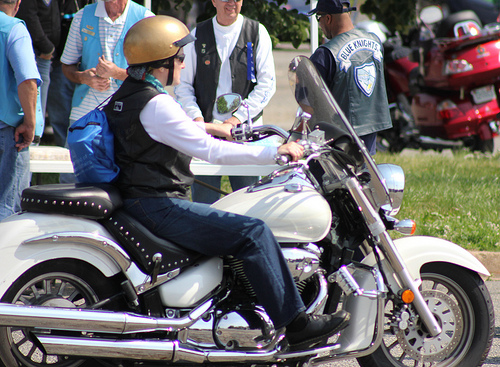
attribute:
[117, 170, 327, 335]
pants — long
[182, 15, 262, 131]
vest — dark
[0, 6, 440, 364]
people — gathered, together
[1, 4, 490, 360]
people — enjoying the day, out in sunshine, part of club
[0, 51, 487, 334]
motorcycle — white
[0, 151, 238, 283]
seat — black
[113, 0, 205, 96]
helmet — black, golden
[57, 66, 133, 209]
bag — blue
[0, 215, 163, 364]
wheel — black, back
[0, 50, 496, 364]
motorcycle — black, white, handle, big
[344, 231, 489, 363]
wheel — black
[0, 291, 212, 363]
pipe — exhaust, metal, gray, large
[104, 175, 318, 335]
jeans — blue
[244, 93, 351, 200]
bar — handle, chrome, metal, gray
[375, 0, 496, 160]
motorcycle — red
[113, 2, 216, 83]
helmet — brown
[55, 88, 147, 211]
backpack — blue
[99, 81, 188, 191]
vest — blue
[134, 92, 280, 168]
shirt — white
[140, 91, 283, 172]
shirt — white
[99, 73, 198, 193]
vest — blue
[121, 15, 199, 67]
helmet — gold, black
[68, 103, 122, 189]
backpack — blue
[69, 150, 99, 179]
lettering — white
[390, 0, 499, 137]
motorcycle — red, black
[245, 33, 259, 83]
ribbon — blue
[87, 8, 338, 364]
cyclist — gold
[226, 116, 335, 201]
bars — handle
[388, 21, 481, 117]
motorcycle — red, back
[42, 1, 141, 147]
vest — light, blue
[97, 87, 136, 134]
emblem — back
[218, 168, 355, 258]
tank — white, gas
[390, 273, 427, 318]
reflector — orange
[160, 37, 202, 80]
sunglasses — dark